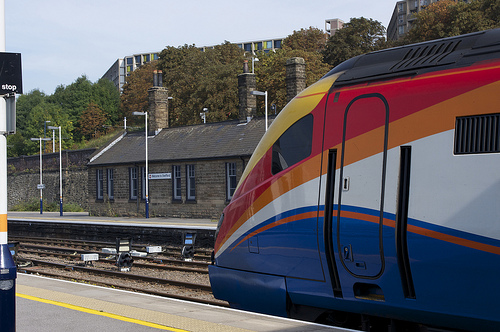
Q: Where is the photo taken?
A: Train station.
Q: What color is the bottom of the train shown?
A: Blue.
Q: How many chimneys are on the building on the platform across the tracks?
A: Three.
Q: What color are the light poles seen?
A: White.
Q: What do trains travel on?
A: Tracks.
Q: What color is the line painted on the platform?
A: Yellow.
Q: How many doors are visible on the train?
A: One.